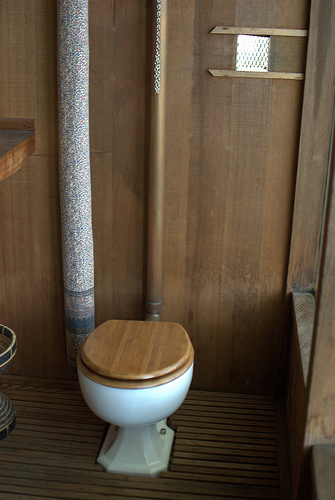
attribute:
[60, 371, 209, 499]
toilet is white — brown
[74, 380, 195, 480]
porcelain base — procelain 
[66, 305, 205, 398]
toilet seat top — wooden-like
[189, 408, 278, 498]
brown wood panels — floorboards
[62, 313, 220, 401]
toilet seat — wood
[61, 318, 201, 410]
toilet sink lid — white, brown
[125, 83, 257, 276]
wall — brown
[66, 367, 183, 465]
toilet — white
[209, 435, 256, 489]
floor — wood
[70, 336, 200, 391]
seat — brown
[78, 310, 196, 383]
top — brown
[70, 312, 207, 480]
toilet bowl — white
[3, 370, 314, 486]
floor — wooden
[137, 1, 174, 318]
pipe — metallic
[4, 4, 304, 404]
wall — brown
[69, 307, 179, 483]
sink — closed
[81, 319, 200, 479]
sink — white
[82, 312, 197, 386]
lid — wooden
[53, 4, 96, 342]
poll — white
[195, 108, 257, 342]
wall — wooden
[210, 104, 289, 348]
wall — wooden, brown